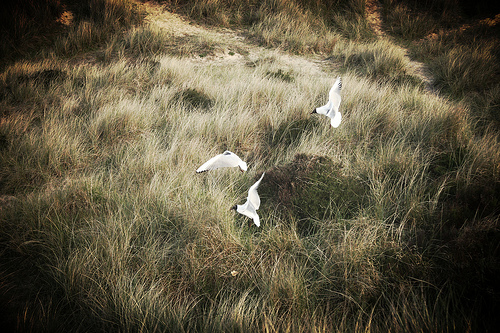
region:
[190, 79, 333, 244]
birds flying in the field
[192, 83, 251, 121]
the hay is tall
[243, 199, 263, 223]
the bird is white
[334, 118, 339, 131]
wing of the bird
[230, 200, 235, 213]
the beak is black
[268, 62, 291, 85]
dark green in field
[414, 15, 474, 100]
the field is shadowed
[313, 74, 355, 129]
the bird is flying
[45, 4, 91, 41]
flower in the field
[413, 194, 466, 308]
dark part of field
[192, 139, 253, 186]
white bird above the grass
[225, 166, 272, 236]
white bird above the grass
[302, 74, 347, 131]
white bird above the grass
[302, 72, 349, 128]
white bird with a black face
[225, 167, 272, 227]
white bird with a black face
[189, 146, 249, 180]
white bird with a black face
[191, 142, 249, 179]
white bird with black wing tips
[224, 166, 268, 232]
white bird with black wing tips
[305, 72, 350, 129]
white bird with black wing tips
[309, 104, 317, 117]
head of a white bird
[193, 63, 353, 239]
the birds in the air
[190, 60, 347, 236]
the white flock of birds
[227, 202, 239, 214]
the black face of the bird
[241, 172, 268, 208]
the wing of the bird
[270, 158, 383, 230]
the grass on the hill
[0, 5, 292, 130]
the long brown grass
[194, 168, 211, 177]
the black tips of the wings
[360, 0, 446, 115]
the path on the hill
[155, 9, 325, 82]
the patch in the grassy hill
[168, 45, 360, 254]
the white flock of flying birds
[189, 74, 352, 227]
Three birds flying in mid air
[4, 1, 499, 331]
Thick grass in the back ground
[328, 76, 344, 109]
wings of the bird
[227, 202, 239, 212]
head of the bird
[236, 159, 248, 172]
tail of the bird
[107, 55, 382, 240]
Light grass area in the field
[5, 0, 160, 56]
dark grass in the field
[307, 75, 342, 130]
Bird gliding in mid air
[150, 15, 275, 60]
thin grass area in the field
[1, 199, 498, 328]
Thick foliage of grass in the field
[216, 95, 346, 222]
birds flying bellow the grass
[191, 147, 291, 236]
the birds are white in color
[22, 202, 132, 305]
the shadow of adjacent trees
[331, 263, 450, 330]
shadow is black in color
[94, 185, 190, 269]
the grasses are tall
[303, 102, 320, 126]
the birds beak is black in color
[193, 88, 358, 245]
birds are three in number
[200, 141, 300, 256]
birds are on the grass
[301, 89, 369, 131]
bird is in the air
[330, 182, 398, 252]
grasses are green and white in color